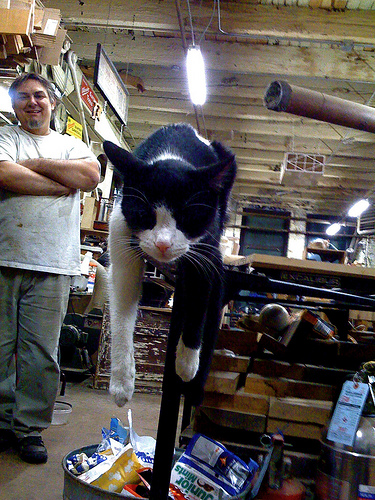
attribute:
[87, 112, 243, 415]
cat — black, white, sleeping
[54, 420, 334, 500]
box — full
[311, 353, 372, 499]
fire extinguisher — silver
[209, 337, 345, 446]
lumber — cut, wood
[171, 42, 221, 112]
light — flourescent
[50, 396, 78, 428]
bowl — empty, plastic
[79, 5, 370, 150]
ceiling — unfinished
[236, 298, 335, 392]
ball and hitch — rusted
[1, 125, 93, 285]
shirt — dirty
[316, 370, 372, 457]
tag — white, blue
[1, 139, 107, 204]
arms — crossed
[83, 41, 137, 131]
sign — hanging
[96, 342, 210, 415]
paws — black, white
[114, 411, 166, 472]
box — empty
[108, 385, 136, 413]
foot — white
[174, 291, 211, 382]
foot — black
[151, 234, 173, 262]
nose — pink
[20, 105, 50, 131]
moustache — salt, pepper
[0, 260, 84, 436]
blue jeans — dirty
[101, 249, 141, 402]
leg — white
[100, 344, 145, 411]
paw — white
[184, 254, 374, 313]
furniture — wood